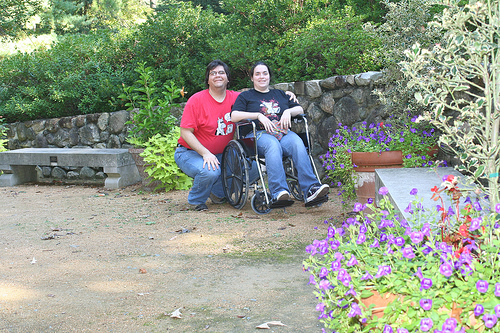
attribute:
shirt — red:
[172, 81, 229, 151]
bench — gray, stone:
[16, 146, 136, 214]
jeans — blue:
[263, 134, 303, 194]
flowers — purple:
[306, 199, 467, 327]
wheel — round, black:
[212, 145, 252, 215]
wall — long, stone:
[4, 101, 125, 164]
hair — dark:
[195, 57, 262, 89]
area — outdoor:
[25, 24, 465, 330]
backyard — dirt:
[18, 204, 284, 322]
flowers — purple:
[328, 229, 476, 329]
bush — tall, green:
[120, 85, 200, 201]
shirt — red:
[179, 101, 249, 169]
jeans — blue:
[165, 148, 277, 227]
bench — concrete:
[2, 130, 154, 190]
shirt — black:
[225, 87, 315, 126]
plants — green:
[109, 73, 199, 157]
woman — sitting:
[186, 52, 327, 184]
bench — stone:
[21, 133, 154, 173]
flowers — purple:
[294, 226, 445, 326]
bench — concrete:
[3, 122, 158, 210]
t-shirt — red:
[168, 86, 244, 146]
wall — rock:
[312, 67, 428, 154]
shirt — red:
[176, 87, 283, 174]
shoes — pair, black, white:
[260, 184, 338, 209]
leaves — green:
[108, 60, 209, 204]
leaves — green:
[110, 52, 203, 196]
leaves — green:
[34, 36, 138, 96]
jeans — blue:
[246, 124, 322, 193]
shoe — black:
[302, 177, 331, 209]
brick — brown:
[348, 146, 408, 171]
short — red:
[173, 88, 240, 148]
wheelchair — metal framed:
[232, 114, 281, 212]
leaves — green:
[194, 30, 230, 56]